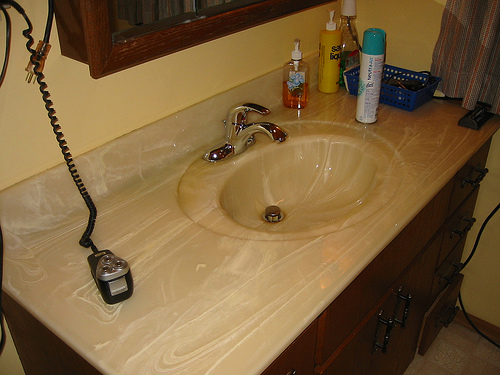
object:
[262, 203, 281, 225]
stopper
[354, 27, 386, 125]
can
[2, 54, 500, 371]
counter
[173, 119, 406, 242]
bathroom sink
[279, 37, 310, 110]
bottle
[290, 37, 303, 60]
pump